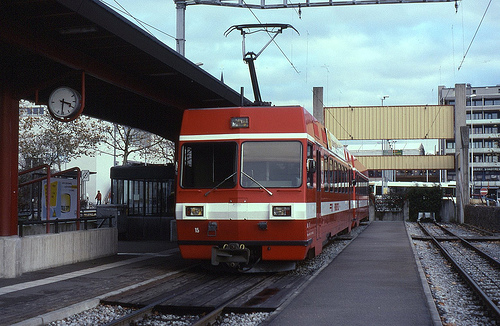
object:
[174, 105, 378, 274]
train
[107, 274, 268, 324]
track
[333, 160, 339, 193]
window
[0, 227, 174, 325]
platform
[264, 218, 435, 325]
pavement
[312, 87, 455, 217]
building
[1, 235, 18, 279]
block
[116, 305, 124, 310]
rock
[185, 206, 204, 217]
light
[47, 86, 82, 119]
clock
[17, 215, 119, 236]
railing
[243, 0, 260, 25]
wire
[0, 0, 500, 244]
background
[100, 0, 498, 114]
sky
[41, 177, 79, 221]
sign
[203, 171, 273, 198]
wiper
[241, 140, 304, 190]
windshield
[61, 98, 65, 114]
hand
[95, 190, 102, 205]
person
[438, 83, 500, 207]
building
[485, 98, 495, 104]
window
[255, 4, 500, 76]
cloud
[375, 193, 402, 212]
car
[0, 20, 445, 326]
station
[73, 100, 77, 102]
dial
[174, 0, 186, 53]
pole